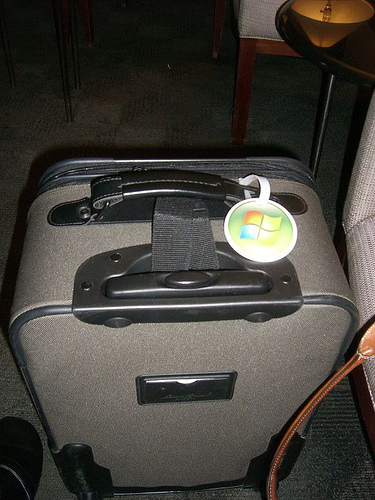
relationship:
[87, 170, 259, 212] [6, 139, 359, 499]
suitcase handle on luggage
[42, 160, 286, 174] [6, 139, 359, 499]
zipper on luggage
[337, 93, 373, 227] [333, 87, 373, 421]
arm of sofa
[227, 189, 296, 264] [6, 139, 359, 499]
tag on luggage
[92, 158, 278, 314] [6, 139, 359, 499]
handles on luggage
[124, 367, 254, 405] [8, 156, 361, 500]
slot on suitcase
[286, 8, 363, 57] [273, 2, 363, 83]
lamp on table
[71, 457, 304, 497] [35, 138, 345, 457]
wheels on luggage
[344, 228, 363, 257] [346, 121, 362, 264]
cloth on seat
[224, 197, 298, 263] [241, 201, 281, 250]
tag with symbol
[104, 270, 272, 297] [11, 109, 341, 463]
pull handle on suitcase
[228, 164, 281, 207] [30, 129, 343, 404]
clip attavhed to suitcase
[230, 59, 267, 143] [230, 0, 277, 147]
leg of a chair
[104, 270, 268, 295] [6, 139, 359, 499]
pull handle retracted into luggage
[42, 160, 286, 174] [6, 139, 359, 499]
zipper closing luggage